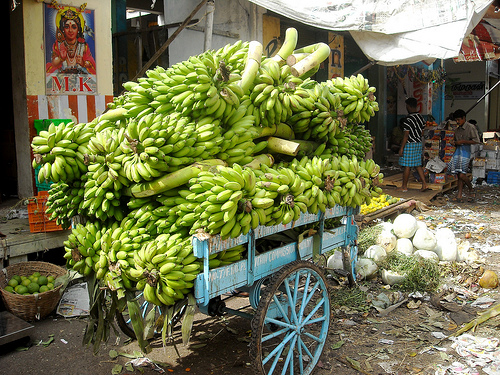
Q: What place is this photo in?
A: It is at the street.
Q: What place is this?
A: It is a street.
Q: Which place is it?
A: It is a street.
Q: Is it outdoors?
A: Yes, it is outdoors.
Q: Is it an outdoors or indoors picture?
A: It is outdoors.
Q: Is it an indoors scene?
A: No, it is outdoors.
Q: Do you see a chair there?
A: No, there are no chairs.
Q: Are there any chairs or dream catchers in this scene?
A: No, there are no chairs or dream catchers.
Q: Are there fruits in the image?
A: Yes, there is a fruit.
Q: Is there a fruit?
A: Yes, there is a fruit.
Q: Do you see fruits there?
A: Yes, there is a fruit.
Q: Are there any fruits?
A: Yes, there is a fruit.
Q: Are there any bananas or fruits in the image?
A: Yes, there is a fruit.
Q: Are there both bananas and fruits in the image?
A: Yes, there are both a fruit and bananas.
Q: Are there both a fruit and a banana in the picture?
A: Yes, there are both a fruit and a banana.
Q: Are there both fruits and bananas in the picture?
A: Yes, there are both a fruit and bananas.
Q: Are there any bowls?
A: No, there are no bowls.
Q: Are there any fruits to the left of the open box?
A: Yes, there is a fruit to the left of the box.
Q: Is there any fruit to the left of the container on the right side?
A: Yes, there is a fruit to the left of the box.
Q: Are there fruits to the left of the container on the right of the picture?
A: Yes, there is a fruit to the left of the box.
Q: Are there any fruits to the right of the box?
A: No, the fruit is to the left of the box.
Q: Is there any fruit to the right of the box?
A: No, the fruit is to the left of the box.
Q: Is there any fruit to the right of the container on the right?
A: No, the fruit is to the left of the box.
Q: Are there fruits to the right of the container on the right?
A: No, the fruit is to the left of the box.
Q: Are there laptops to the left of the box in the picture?
A: No, there is a fruit to the left of the box.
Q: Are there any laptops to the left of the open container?
A: No, there is a fruit to the left of the box.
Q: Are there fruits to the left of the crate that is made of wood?
A: Yes, there is a fruit to the left of the crate.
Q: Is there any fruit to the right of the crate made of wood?
A: No, the fruit is to the left of the crate.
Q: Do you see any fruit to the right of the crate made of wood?
A: No, the fruit is to the left of the crate.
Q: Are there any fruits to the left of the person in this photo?
A: Yes, there is a fruit to the left of the person.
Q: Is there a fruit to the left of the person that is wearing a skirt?
A: Yes, there is a fruit to the left of the person.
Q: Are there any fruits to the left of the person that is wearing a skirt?
A: Yes, there is a fruit to the left of the person.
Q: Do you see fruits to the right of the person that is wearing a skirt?
A: No, the fruit is to the left of the person.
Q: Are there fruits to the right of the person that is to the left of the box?
A: No, the fruit is to the left of the person.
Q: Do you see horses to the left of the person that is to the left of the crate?
A: No, there is a fruit to the left of the person.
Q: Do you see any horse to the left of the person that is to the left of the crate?
A: No, there is a fruit to the left of the person.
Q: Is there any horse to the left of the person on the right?
A: No, there is a fruit to the left of the person.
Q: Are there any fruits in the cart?
A: Yes, there is a fruit in the cart.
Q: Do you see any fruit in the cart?
A: Yes, there is a fruit in the cart.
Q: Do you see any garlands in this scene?
A: No, there are no garlands.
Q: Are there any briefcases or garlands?
A: No, there are no garlands or briefcases.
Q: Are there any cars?
A: No, there are no cars.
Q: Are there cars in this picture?
A: No, there are no cars.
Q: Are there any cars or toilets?
A: No, there are no cars or toilets.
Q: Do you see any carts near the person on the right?
A: Yes, there is a cart near the person.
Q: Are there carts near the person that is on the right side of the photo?
A: Yes, there is a cart near the person.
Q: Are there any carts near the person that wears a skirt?
A: Yes, there is a cart near the person.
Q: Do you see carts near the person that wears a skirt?
A: Yes, there is a cart near the person.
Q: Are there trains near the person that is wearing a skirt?
A: No, there is a cart near the person.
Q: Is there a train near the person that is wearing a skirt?
A: No, there is a cart near the person.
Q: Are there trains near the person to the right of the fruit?
A: No, there is a cart near the person.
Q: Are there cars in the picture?
A: No, there are no cars.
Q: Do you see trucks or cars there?
A: No, there are no cars or trucks.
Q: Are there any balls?
A: No, there are no balls.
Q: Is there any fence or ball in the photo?
A: No, there are no balls or fences.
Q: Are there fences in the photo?
A: No, there are no fences.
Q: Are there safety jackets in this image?
A: No, there are no safety jackets.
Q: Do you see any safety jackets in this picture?
A: No, there are no safety jackets.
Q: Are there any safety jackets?
A: No, there are no safety jackets.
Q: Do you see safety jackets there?
A: No, there are no safety jackets.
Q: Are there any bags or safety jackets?
A: No, there are no safety jackets or bags.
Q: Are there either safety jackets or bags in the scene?
A: No, there are no safety jackets or bags.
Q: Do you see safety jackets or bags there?
A: No, there are no safety jackets or bags.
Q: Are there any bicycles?
A: No, there are no bicycles.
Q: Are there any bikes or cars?
A: No, there are no bikes or cars.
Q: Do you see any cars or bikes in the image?
A: No, there are no bikes or cars.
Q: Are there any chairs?
A: No, there are no chairs.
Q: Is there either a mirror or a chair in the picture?
A: No, there are no chairs or mirrors.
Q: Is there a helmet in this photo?
A: No, there are no helmets.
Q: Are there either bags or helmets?
A: No, there are no helmets or bags.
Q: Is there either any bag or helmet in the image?
A: No, there are no helmets or bags.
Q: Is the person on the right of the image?
A: Yes, the person is on the right of the image.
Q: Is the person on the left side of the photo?
A: No, the person is on the right of the image.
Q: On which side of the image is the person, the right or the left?
A: The person is on the right of the image.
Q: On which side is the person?
A: The person is on the right of the image.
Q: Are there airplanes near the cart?
A: No, there is a person near the cart.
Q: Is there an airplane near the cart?
A: No, there is a person near the cart.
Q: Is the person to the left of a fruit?
A: No, the person is to the right of a fruit.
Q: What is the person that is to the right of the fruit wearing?
A: The person is wearing a skirt.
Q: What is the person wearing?
A: The person is wearing a skirt.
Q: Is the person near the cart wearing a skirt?
A: Yes, the person is wearing a skirt.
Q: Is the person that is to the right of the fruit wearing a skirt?
A: Yes, the person is wearing a skirt.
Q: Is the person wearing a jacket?
A: No, the person is wearing a skirt.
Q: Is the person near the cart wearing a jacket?
A: No, the person is wearing a skirt.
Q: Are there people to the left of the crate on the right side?
A: Yes, there is a person to the left of the crate.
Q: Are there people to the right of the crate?
A: No, the person is to the left of the crate.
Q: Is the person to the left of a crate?
A: Yes, the person is to the left of a crate.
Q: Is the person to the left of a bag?
A: No, the person is to the left of a crate.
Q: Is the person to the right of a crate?
A: No, the person is to the left of a crate.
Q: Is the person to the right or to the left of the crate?
A: The person is to the left of the crate.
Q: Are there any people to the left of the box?
A: Yes, there is a person to the left of the box.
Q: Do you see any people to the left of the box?
A: Yes, there is a person to the left of the box.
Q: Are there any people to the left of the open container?
A: Yes, there is a person to the left of the box.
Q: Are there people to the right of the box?
A: No, the person is to the left of the box.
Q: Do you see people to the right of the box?
A: No, the person is to the left of the box.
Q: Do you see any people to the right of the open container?
A: No, the person is to the left of the box.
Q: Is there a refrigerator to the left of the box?
A: No, there is a person to the left of the box.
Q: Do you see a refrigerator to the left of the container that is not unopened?
A: No, there is a person to the left of the box.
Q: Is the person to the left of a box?
A: Yes, the person is to the left of a box.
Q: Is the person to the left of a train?
A: No, the person is to the left of a box.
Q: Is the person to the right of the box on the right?
A: No, the person is to the left of the box.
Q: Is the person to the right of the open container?
A: No, the person is to the left of the box.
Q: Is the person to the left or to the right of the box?
A: The person is to the left of the box.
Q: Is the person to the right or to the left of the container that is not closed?
A: The person is to the left of the box.